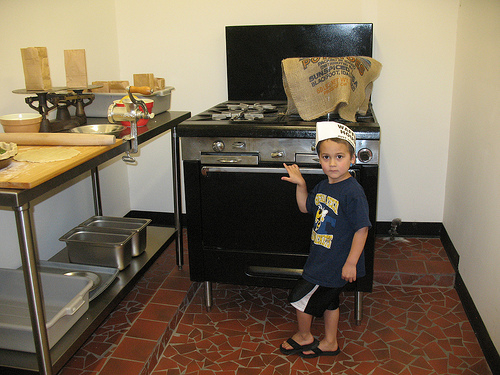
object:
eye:
[322, 155, 330, 160]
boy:
[277, 120, 373, 360]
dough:
[0, 129, 118, 146]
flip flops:
[278, 332, 341, 359]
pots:
[56, 212, 153, 271]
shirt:
[300, 176, 372, 288]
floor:
[119, 309, 275, 375]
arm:
[341, 188, 374, 266]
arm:
[295, 180, 326, 214]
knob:
[212, 139, 226, 152]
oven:
[172, 21, 382, 327]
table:
[0, 109, 191, 374]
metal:
[12, 84, 105, 132]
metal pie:
[204, 278, 214, 312]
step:
[96, 277, 194, 375]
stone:
[115, 335, 157, 365]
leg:
[90, 165, 103, 215]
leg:
[169, 125, 185, 271]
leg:
[13, 204, 51, 374]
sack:
[281, 55, 384, 122]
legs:
[287, 268, 342, 343]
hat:
[314, 121, 357, 153]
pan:
[68, 122, 127, 136]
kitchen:
[0, 0, 497, 375]